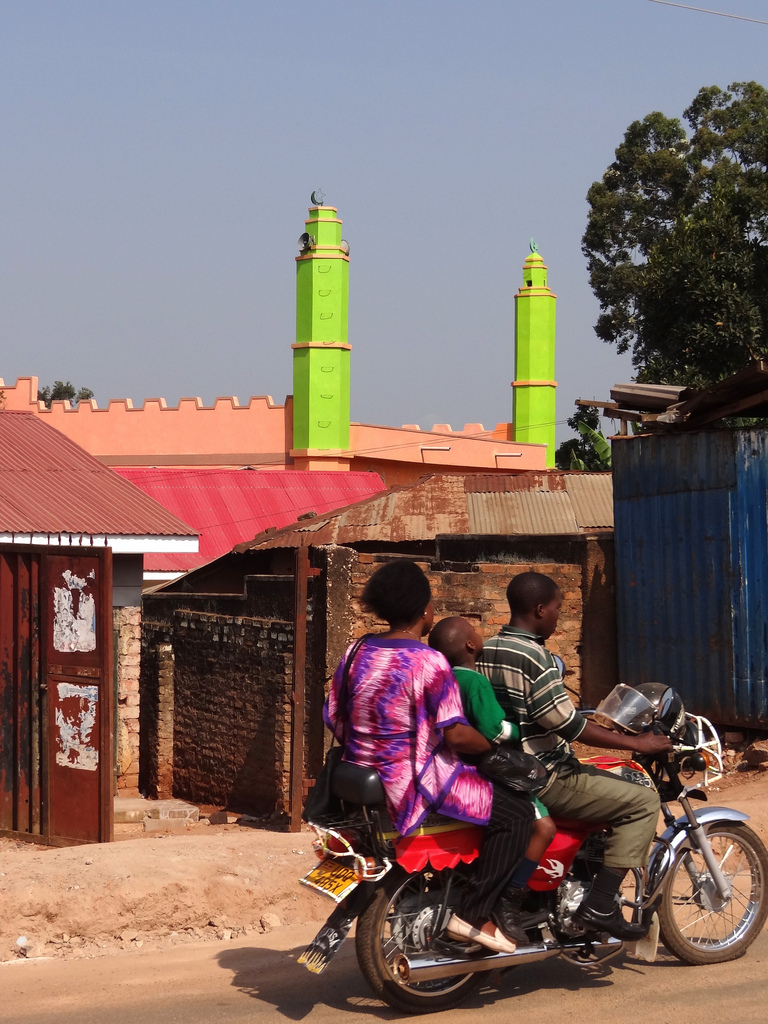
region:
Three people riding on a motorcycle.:
[312, 555, 678, 958]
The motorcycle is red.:
[295, 702, 767, 1016]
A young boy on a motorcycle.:
[422, 611, 559, 948]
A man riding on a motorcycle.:
[474, 569, 676, 944]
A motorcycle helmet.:
[595, 676, 689, 749]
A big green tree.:
[576, 76, 767, 429]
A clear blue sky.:
[2, 1, 767, 446]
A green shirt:
[445, 659, 519, 751]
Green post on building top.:
[293, 205, 364, 448]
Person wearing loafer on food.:
[448, 917, 521, 959]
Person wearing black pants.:
[480, 798, 515, 963]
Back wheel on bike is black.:
[369, 878, 467, 1001]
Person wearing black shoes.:
[499, 898, 535, 949]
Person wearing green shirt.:
[466, 670, 519, 752]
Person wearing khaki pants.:
[554, 765, 675, 864]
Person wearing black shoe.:
[567, 894, 627, 931]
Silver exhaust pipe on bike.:
[391, 933, 627, 973]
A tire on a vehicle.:
[358, 862, 489, 1014]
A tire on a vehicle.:
[650, 816, 767, 959]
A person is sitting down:
[428, 613, 520, 740]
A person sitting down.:
[322, 557, 537, 955]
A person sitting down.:
[476, 569, 658, 943]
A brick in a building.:
[349, 570, 373, 584]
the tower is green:
[296, 193, 353, 468]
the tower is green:
[513, 242, 556, 463]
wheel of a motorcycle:
[359, 865, 486, 1009]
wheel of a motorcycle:
[660, 812, 766, 957]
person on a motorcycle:
[331, 571, 537, 963]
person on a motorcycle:
[428, 615, 526, 765]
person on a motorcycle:
[478, 570, 677, 937]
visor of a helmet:
[592, 684, 650, 731]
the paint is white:
[54, 574, 96, 649]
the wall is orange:
[4, 378, 545, 469]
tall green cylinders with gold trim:
[293, 188, 356, 454]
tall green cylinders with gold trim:
[513, 244, 564, 468]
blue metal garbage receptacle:
[603, 421, 766, 753]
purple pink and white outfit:
[321, 636, 497, 831]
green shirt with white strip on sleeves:
[443, 662, 524, 748]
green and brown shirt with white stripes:
[466, 623, 592, 782]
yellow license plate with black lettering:
[305, 853, 364, 899]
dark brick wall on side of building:
[145, 610, 294, 827]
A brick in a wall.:
[235, 671, 263, 688]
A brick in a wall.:
[224, 709, 238, 727]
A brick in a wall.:
[183, 681, 212, 691]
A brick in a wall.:
[117, 650, 143, 669]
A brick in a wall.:
[115, 639, 144, 651]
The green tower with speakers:
[291, 203, 351, 453]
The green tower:
[512, 249, 554, 467]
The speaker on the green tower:
[294, 232, 311, 255]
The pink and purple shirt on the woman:
[318, 632, 488, 832]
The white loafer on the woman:
[444, 913, 516, 955]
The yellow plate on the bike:
[306, 860, 358, 896]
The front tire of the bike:
[662, 808, 767, 965]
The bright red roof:
[112, 468, 385, 570]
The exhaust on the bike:
[391, 935, 627, 994]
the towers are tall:
[211, 192, 630, 483]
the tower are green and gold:
[244, 72, 623, 534]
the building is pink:
[86, 375, 381, 496]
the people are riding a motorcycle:
[317, 509, 707, 897]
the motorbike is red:
[410, 779, 759, 955]